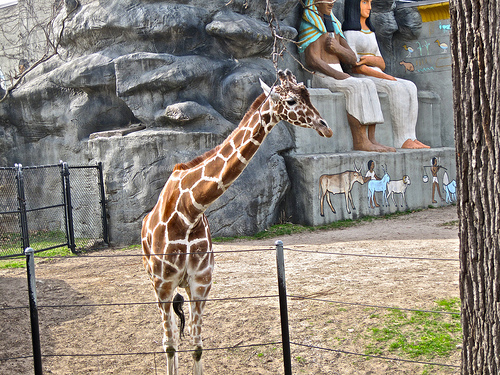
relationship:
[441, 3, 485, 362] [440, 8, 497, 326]
tree has trunk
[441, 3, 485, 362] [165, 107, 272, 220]
tree next to giraffe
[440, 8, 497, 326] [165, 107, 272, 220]
trunk next to giraffe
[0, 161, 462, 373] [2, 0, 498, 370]
fence around enclosure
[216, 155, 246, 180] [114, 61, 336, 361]
spot on giraffe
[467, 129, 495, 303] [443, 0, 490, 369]
gray bark on tree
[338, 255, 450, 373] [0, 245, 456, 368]
grass on dirt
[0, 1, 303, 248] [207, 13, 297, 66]
wall of rock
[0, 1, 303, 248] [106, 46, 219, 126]
wall of rock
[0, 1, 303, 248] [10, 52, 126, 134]
wall of rock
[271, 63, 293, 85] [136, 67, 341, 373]
horns on giraffe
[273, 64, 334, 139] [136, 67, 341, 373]
head on giraffe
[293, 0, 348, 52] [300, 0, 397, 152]
head dress on statue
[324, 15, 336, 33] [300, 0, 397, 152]
beard on statue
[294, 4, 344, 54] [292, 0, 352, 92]
dress on man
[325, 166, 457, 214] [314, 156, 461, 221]
painting on wall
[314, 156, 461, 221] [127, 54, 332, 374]
wall behind giraffe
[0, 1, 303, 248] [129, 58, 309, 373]
wall behind giraffe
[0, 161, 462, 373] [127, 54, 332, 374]
fence surrounding giraffe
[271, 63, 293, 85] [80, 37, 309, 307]
horns of giraffe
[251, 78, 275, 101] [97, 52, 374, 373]
ear on giraffe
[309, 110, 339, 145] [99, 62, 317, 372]
nose on giraffe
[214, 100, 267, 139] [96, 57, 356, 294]
mane on giraffe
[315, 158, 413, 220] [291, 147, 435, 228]
picture on wall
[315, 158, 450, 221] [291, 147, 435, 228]
picture on wall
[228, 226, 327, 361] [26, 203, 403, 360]
pole for fence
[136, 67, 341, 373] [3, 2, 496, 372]
giraffe in pen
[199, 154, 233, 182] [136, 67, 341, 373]
spot on giraffe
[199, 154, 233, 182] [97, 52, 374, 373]
spot on giraffe